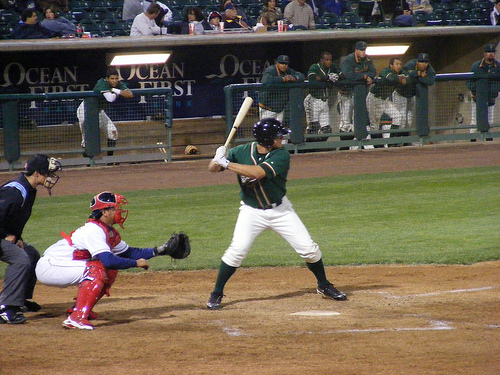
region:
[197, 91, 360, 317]
guy wearing black helmet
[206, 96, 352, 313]
guy wearing green shirt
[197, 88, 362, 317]
guy wearing white pants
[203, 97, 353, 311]
guy wearing tennis shoes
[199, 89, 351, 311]
guy holding baseball bat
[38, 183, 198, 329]
guy wearing a red helmet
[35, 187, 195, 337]
guy wearing red shoes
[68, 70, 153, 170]
guy leaning on fence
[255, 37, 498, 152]
guys watching the game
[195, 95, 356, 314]
guy wearing green socks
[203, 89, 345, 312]
a baseball player at bat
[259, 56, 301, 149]
a baseball player standing at rail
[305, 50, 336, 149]
a baseball player standing at rail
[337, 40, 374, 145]
a baseball player standing at rail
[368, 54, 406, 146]
a baseball player standing at rail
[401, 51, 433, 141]
a baseball player standing at rail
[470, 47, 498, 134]
a baseball player standing at rail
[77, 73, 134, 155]
a baseball player standing at rail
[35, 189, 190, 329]
a baseball catcher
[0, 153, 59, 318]
a baseball umpire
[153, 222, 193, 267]
a black baseball glove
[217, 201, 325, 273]
white baseball uniform pants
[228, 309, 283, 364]
white line painted on the ground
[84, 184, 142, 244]
a man wearing a mask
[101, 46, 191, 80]
a light in the dug out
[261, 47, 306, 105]
a man wearing a baseball hat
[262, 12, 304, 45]
a drink sitting on the table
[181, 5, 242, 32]
fans watching the baseball game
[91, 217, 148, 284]
a man wearing a blue shirt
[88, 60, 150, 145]
a man leaning on a fence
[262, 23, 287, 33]
soda cup on top of dugout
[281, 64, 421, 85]
baseball players leaning on the fence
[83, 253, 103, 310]
catcher has red safety pads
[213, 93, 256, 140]
baseball bat is tan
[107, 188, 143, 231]
catcher is wearing a mask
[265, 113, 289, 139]
batting helmet is blue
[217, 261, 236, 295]
player's socks are green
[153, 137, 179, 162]
bats in the dugout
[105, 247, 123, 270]
catcher's sleeves are blue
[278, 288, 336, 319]
home plate is white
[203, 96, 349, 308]
batter about to hit the ball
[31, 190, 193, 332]
catcher crouching behind the batter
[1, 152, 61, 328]
umpire crouching behind the catcher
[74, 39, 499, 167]
players standing behind the fence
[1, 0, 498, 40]
spectators in the stands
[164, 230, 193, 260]
a black baseball glove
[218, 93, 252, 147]
a wooden bat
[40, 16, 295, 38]
drinks sitting in front of the spectators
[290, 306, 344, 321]
home plate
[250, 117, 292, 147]
a black batting helmet